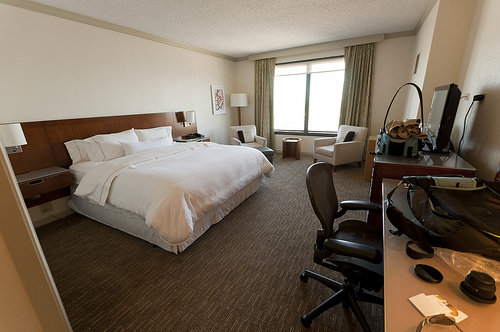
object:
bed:
[67, 142, 266, 253]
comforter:
[74, 131, 273, 243]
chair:
[299, 160, 384, 332]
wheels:
[297, 269, 312, 284]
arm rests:
[322, 238, 383, 265]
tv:
[425, 83, 460, 150]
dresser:
[359, 137, 474, 224]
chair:
[312, 124, 366, 171]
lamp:
[228, 94, 249, 130]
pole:
[237, 106, 241, 126]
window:
[271, 56, 340, 133]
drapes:
[253, 41, 374, 150]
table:
[280, 136, 301, 161]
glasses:
[416, 312, 464, 332]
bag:
[376, 80, 423, 157]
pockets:
[387, 139, 407, 159]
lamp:
[0, 122, 30, 156]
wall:
[0, 1, 244, 230]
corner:
[228, 57, 246, 136]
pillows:
[119, 136, 173, 159]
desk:
[381, 175, 498, 331]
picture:
[211, 84, 227, 116]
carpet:
[39, 149, 377, 327]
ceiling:
[24, 1, 437, 57]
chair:
[231, 125, 267, 146]